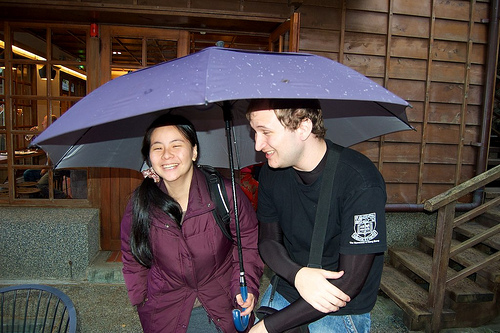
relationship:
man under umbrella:
[245, 99, 387, 333] [31, 47, 417, 172]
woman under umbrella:
[120, 113, 267, 332] [31, 47, 417, 172]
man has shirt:
[245, 99, 387, 333] [260, 141, 389, 315]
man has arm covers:
[245, 99, 387, 333] [257, 221, 374, 333]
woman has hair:
[120, 113, 267, 332] [132, 113, 200, 267]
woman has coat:
[120, 113, 267, 332] [119, 172, 263, 333]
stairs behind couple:
[380, 162, 499, 333] [119, 99, 385, 333]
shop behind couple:
[1, 0, 298, 284] [119, 99, 385, 333]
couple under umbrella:
[119, 99, 385, 333] [31, 47, 417, 172]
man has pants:
[245, 99, 387, 333] [255, 281, 371, 333]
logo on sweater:
[349, 212, 380, 246] [258, 142, 388, 333]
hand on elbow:
[293, 266, 350, 314] [327, 268, 362, 299]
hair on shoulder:
[132, 113, 200, 267] [123, 185, 169, 221]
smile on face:
[159, 162, 181, 174] [144, 123, 197, 180]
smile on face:
[262, 149, 275, 159] [246, 103, 318, 170]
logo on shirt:
[349, 212, 380, 246] [260, 141, 389, 315]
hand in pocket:
[128, 284, 152, 314] [129, 280, 156, 315]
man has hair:
[245, 99, 387, 333] [268, 97, 330, 140]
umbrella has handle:
[31, 47, 417, 172] [224, 105, 252, 332]